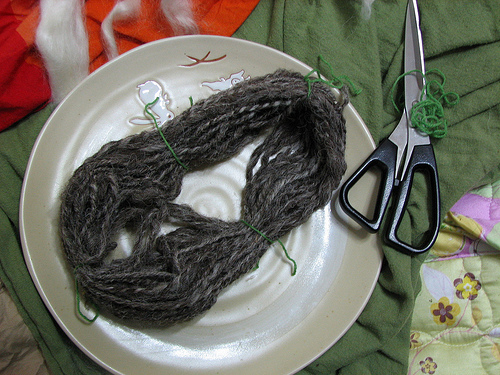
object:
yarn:
[303, 57, 365, 103]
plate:
[20, 36, 394, 374]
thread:
[60, 64, 347, 329]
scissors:
[339, 1, 446, 254]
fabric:
[60, 72, 344, 328]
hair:
[2, 2, 260, 129]